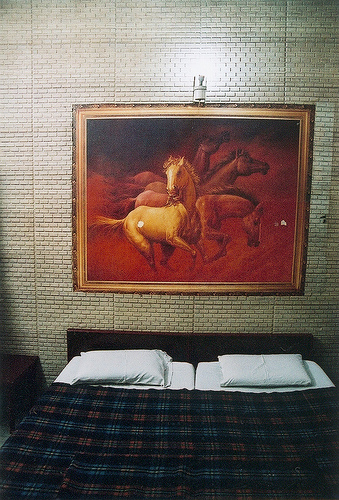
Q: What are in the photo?
A: Horses.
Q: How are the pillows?
A: Flat.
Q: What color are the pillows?
A: White.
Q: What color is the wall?
A: Gray.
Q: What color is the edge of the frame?
A: Brown.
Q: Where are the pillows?
A: Bed.